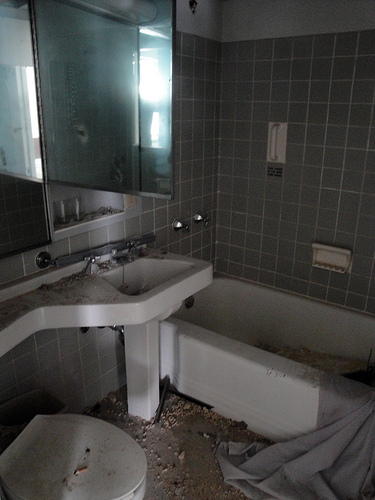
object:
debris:
[107, 380, 247, 444]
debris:
[38, 273, 96, 305]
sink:
[78, 239, 215, 330]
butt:
[74, 466, 88, 476]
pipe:
[110, 325, 125, 335]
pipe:
[79, 326, 89, 333]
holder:
[312, 242, 354, 274]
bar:
[270, 122, 279, 160]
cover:
[0, 414, 147, 500]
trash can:
[0, 387, 68, 448]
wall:
[3, 0, 214, 455]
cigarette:
[74, 466, 88, 476]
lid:
[0, 413, 150, 499]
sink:
[2, 235, 214, 422]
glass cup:
[54, 200, 66, 223]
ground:
[307, 80, 352, 126]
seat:
[0, 416, 150, 499]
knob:
[192, 210, 210, 226]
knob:
[172, 217, 192, 232]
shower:
[213, 1, 375, 317]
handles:
[172, 210, 209, 233]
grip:
[267, 122, 288, 163]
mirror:
[0, 2, 175, 254]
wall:
[213, 29, 373, 318]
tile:
[310, 56, 333, 80]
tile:
[307, 101, 329, 124]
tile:
[303, 144, 324, 167]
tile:
[253, 81, 271, 102]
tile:
[264, 197, 282, 221]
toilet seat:
[0, 413, 147, 498]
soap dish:
[312, 243, 353, 273]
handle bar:
[266, 121, 288, 163]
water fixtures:
[172, 211, 210, 233]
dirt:
[63, 444, 114, 489]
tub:
[159, 277, 375, 449]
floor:
[70, 383, 264, 499]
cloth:
[216, 371, 374, 498]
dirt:
[251, 338, 363, 371]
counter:
[0, 248, 213, 356]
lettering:
[267, 165, 283, 176]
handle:
[173, 220, 191, 233]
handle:
[193, 214, 210, 226]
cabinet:
[32, 0, 179, 243]